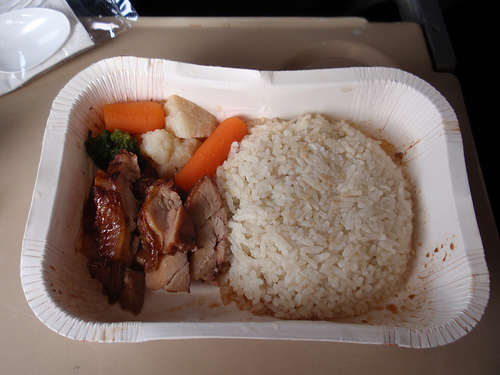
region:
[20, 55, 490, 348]
Food is in a tray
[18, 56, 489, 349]
The tray is white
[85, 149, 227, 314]
Some pieces of chicken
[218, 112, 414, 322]
Pile of white rice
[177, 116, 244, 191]
The carrot is orange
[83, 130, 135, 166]
A piece of broccoli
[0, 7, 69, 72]
The spoon is white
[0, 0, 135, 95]
Spoon and napkin in plastic wrapper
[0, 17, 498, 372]
Table is beige colored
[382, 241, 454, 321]
Sauce on the tray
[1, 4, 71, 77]
a plastic spoon in a wrapper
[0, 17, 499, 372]
a beige tray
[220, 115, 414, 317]
a serving of white rice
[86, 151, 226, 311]
beef cubes with brown sauce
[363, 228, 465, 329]
brown sauce on the side of a white container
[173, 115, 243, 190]
a baby carrot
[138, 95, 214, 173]
bots of cauliflower between two carrots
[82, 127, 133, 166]
a bit of broccoli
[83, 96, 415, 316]
rice, beef and veggie in a plastic container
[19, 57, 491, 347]
a white plastic container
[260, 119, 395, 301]
Circle of rice in a plate.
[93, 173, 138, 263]
Cut up pieces of meat.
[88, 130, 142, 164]
Small part of broccoli next to meat.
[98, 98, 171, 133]
Small part of cut up carrot.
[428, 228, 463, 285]
Meat sauce on the side of plate.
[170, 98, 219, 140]
Cut up cauliflower in the corner.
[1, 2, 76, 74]
Small part of plastic spoon in the corner.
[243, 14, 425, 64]
Tan folding table holding food.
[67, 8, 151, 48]
Small piece of napkin wrapped in plastic.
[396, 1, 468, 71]
Silver part of table attached to a table.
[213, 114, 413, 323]
portion of cooked white rice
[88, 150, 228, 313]
kalua pork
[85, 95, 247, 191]
mixed cooked vegetables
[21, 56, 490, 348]
to go container with meat rick and vegetables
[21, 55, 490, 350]
meal in bottom half of to go container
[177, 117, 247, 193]
cooked carrot piece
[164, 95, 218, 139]
cooked cauliflower piece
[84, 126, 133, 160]
piece of cooked chopped broccoli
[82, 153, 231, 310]
cooked meat with skin on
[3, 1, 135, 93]
plastic to go spoon and napkin in plastic wrap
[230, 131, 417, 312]
serving of white rice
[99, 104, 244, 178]
mixed veggies in container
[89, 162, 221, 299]
chicken with sauce in container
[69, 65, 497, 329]
white container with food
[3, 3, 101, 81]
plastic spoon in wrap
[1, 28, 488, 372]
beige tray with food on it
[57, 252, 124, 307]
sauce inside white container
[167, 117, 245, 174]
baby carrot beside rice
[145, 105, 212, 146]
cauliflower beside baby carrot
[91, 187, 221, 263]
crispy chicken with glaze